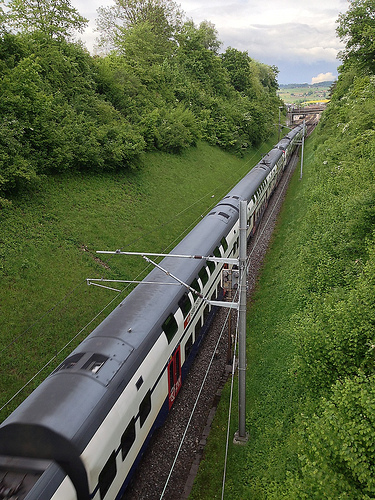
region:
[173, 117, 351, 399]
the rail is in between two bushes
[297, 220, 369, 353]
the bush on the left side of tghe rail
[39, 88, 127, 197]
bush on the right side of the rail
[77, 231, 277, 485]
the train is in motion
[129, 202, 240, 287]
the surface is grey in color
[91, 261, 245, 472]
the train is white in color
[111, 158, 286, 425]
the train is very long in length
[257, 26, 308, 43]
sky is covered with white clouds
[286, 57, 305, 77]
sky is blue in color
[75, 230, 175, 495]
train on the track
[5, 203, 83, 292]
grass on the field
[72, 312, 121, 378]
top of the train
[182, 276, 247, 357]
side of the train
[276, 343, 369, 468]
leaves on the tree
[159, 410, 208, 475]
track for the train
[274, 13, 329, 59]
clouds in the sky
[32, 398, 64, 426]
the roof is black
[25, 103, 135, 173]
trees on the hill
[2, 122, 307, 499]
a long train on the track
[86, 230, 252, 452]
a pole with some scaffolding on the top of it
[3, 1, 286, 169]
a whole lot of trees with some green leaves on the hill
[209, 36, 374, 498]
the green grassy and leafy hill to the right of the train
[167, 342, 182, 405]
the red doors with some graffiti on it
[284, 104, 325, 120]
a bridge over the track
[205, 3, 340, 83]
some white clouds in the sunny sky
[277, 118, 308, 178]
another metal pole with scaffolding on it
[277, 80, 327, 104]
a field with a lot of grass on it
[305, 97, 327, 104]
a yellow bridge by the field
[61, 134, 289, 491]
white and grey train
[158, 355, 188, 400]
train has red doors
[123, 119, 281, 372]
power lines over train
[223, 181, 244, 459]
grey poles near train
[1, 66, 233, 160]
green trees atop hills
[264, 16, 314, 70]
white and grey sky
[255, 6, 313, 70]
thick clouds in sky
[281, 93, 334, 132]
brown bridge over train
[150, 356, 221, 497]
grey gravel near train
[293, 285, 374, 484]
green and leafy trees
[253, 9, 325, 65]
this is the sky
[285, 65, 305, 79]
the sky is blue in color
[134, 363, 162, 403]
the train is white in color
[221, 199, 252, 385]
this is a pole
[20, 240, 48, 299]
this is a grass area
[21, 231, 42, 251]
the grass is green in color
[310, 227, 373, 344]
this is a tree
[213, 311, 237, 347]
this is a electrical wire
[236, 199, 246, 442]
A tall metal pole near a train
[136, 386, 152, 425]
A window on a train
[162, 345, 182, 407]
A red door on a train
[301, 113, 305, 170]
A pole near a train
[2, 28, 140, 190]
Green bushes on a hill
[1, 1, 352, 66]
White clouds in a sky